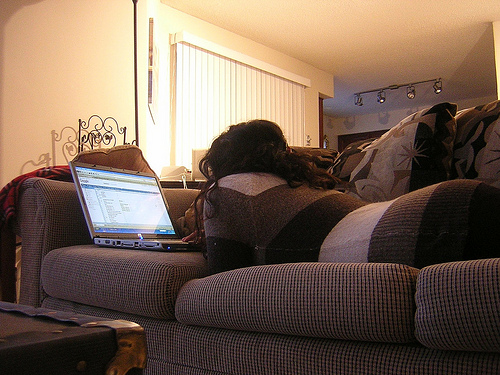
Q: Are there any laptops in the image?
A: Yes, there is a laptop.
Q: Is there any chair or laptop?
A: Yes, there is a laptop.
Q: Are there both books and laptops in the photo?
A: No, there is a laptop but no books.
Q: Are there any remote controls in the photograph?
A: No, there are no remote controls.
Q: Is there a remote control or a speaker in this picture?
A: No, there are no remote controls or speakers.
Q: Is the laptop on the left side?
A: Yes, the laptop is on the left of the image.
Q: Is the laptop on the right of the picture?
A: No, the laptop is on the left of the image.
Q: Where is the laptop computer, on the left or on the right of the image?
A: The laptop computer is on the left of the image.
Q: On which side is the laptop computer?
A: The laptop computer is on the left of the image.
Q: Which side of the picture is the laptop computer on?
A: The laptop computer is on the left of the image.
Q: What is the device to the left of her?
A: The device is a laptop.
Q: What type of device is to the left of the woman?
A: The device is a laptop.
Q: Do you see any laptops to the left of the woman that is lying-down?
A: Yes, there is a laptop to the left of the woman.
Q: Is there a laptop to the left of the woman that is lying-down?
A: Yes, there is a laptop to the left of the woman.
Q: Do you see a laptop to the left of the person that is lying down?
A: Yes, there is a laptop to the left of the woman.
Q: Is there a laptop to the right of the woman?
A: No, the laptop is to the left of the woman.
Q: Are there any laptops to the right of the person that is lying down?
A: No, the laptop is to the left of the woman.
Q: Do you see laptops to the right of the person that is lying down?
A: No, the laptop is to the left of the woman.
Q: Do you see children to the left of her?
A: No, there is a laptop to the left of the woman.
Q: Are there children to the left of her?
A: No, there is a laptop to the left of the woman.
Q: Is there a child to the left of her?
A: No, there is a laptop to the left of the woman.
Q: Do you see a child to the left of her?
A: No, there is a laptop to the left of the woman.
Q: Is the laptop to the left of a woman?
A: Yes, the laptop is to the left of a woman.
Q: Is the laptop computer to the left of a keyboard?
A: No, the laptop computer is to the left of a woman.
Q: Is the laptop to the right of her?
A: No, the laptop is to the left of a woman.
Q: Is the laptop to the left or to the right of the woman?
A: The laptop is to the left of the woman.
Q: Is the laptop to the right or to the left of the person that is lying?
A: The laptop is to the left of the woman.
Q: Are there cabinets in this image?
A: No, there are no cabinets.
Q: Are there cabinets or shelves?
A: No, there are no cabinets or shelves.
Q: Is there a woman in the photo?
A: Yes, there is a woman.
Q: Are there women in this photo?
A: Yes, there is a woman.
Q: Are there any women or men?
A: Yes, there is a woman.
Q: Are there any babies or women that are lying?
A: Yes, the woman is lying.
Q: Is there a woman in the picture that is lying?
A: Yes, there is a woman that is lying.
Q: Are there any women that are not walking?
A: Yes, there is a woman that is lying.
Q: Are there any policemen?
A: No, there are no policemen.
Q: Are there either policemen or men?
A: No, there are no policemen or men.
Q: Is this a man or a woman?
A: This is a woman.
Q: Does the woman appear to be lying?
A: Yes, the woman is lying.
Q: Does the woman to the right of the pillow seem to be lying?
A: Yes, the woman is lying.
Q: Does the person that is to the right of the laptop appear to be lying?
A: Yes, the woman is lying.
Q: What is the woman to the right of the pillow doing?
A: The woman is lying.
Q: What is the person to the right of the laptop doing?
A: The woman is lying.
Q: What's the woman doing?
A: The woman is lying.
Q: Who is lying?
A: The woman is lying.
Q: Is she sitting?
A: No, the woman is lying.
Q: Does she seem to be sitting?
A: No, the woman is lying.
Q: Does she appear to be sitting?
A: No, the woman is lying.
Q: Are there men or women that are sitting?
A: No, there is a woman but she is lying.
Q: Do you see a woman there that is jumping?
A: No, there is a woman but she is lying.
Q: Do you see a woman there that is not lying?
A: No, there is a woman but she is lying.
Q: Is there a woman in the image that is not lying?
A: No, there is a woman but she is lying.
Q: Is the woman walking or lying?
A: The woman is lying.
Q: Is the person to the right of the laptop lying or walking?
A: The woman is lying.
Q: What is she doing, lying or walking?
A: The woman is lying.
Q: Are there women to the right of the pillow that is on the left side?
A: Yes, there is a woman to the right of the pillow.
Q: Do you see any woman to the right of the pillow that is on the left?
A: Yes, there is a woman to the right of the pillow.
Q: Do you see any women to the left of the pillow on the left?
A: No, the woman is to the right of the pillow.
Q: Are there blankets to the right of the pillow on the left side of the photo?
A: No, there is a woman to the right of the pillow.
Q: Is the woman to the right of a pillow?
A: Yes, the woman is to the right of a pillow.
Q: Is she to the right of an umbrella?
A: No, the woman is to the right of a pillow.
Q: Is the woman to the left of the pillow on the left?
A: No, the woman is to the right of the pillow.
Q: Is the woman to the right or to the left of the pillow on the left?
A: The woman is to the right of the pillow.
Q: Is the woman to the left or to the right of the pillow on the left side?
A: The woman is to the right of the pillow.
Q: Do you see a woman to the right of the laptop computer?
A: Yes, there is a woman to the right of the laptop computer.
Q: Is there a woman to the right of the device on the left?
A: Yes, there is a woman to the right of the laptop computer.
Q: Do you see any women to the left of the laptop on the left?
A: No, the woman is to the right of the laptop.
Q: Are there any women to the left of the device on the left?
A: No, the woman is to the right of the laptop.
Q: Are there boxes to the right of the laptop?
A: No, there is a woman to the right of the laptop.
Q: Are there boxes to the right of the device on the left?
A: No, there is a woman to the right of the laptop.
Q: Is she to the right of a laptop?
A: Yes, the woman is to the right of a laptop.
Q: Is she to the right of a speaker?
A: No, the woman is to the right of a laptop.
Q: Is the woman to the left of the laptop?
A: No, the woman is to the right of the laptop.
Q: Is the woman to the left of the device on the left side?
A: No, the woman is to the right of the laptop.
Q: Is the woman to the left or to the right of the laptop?
A: The woman is to the right of the laptop.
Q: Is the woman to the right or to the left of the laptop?
A: The woman is to the right of the laptop.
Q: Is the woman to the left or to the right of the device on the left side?
A: The woman is to the right of the laptop.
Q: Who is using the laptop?
A: The woman is using the laptop.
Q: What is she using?
A: The woman is using a laptop.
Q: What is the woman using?
A: The woman is using a laptop.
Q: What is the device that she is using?
A: The device is a laptop.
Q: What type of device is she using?
A: The woman is using a laptop.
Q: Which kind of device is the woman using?
A: The woman is using a laptop.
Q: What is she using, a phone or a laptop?
A: The woman is using a laptop.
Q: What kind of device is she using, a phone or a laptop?
A: The woman is using a laptop.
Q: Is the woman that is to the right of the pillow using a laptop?
A: Yes, the woman is using a laptop.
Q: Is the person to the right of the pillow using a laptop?
A: Yes, the woman is using a laptop.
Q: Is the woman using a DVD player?
A: No, the woman is using a laptop.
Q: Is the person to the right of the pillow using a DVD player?
A: No, the woman is using a laptop.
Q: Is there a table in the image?
A: Yes, there is a table.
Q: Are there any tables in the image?
A: Yes, there is a table.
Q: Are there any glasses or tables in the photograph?
A: Yes, there is a table.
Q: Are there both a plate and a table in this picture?
A: No, there is a table but no plates.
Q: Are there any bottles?
A: No, there are no bottles.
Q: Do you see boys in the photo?
A: No, there are no boys.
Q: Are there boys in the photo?
A: No, there are no boys.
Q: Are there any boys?
A: No, there are no boys.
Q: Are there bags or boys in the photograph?
A: No, there are no boys or bags.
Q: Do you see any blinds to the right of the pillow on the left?
A: Yes, there are blinds to the right of the pillow.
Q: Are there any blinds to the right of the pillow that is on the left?
A: Yes, there are blinds to the right of the pillow.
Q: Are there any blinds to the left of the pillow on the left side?
A: No, the blinds are to the right of the pillow.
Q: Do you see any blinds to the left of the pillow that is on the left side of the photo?
A: No, the blinds are to the right of the pillow.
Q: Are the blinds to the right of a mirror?
A: No, the blinds are to the right of a pillow.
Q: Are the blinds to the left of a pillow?
A: No, the blinds are to the right of a pillow.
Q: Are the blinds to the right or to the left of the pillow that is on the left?
A: The blinds are to the right of the pillow.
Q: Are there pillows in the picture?
A: Yes, there is a pillow.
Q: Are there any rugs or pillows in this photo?
A: Yes, there is a pillow.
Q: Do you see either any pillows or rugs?
A: Yes, there is a pillow.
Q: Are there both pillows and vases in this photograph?
A: No, there is a pillow but no vases.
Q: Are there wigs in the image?
A: No, there are no wigs.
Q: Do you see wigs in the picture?
A: No, there are no wigs.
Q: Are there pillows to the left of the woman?
A: Yes, there is a pillow to the left of the woman.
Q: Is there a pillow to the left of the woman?
A: Yes, there is a pillow to the left of the woman.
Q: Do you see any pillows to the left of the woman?
A: Yes, there is a pillow to the left of the woman.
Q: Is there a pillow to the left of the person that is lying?
A: Yes, there is a pillow to the left of the woman.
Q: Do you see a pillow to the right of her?
A: No, the pillow is to the left of the woman.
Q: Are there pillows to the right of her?
A: No, the pillow is to the left of the woman.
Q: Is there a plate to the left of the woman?
A: No, there is a pillow to the left of the woman.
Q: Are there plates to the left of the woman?
A: No, there is a pillow to the left of the woman.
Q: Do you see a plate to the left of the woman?
A: No, there is a pillow to the left of the woman.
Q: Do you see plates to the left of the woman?
A: No, there is a pillow to the left of the woman.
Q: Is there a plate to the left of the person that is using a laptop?
A: No, there is a pillow to the left of the woman.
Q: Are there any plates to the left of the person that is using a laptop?
A: No, there is a pillow to the left of the woman.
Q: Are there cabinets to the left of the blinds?
A: No, there is a pillow to the left of the blinds.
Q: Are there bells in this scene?
A: No, there are no bells.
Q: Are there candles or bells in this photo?
A: No, there are no bells or candles.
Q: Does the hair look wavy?
A: Yes, the hair is wavy.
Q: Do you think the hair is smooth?
A: No, the hair is wavy.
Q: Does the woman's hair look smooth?
A: No, the hair is wavy.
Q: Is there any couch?
A: Yes, there is a couch.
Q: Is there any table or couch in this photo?
A: Yes, there is a couch.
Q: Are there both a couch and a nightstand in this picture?
A: No, there is a couch but no nightstands.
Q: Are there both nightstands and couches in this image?
A: No, there is a couch but no nightstands.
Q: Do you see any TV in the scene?
A: No, there are no televisions.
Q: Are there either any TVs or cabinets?
A: No, there are no TVs or cabinets.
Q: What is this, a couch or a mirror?
A: This is a couch.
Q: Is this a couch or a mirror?
A: This is a couch.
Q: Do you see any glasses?
A: No, there are no glasses.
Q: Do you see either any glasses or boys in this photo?
A: No, there are no glasses or boys.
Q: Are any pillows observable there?
A: Yes, there is a pillow.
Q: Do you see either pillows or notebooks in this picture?
A: Yes, there is a pillow.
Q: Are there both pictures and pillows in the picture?
A: No, there is a pillow but no pictures.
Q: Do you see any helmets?
A: No, there are no helmets.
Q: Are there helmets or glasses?
A: No, there are no helmets or glasses.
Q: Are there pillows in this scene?
A: Yes, there is a pillow.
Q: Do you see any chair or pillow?
A: Yes, there is a pillow.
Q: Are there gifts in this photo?
A: No, there are no gifts.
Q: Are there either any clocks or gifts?
A: No, there are no gifts or clocks.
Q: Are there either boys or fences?
A: No, there are no boys or fences.